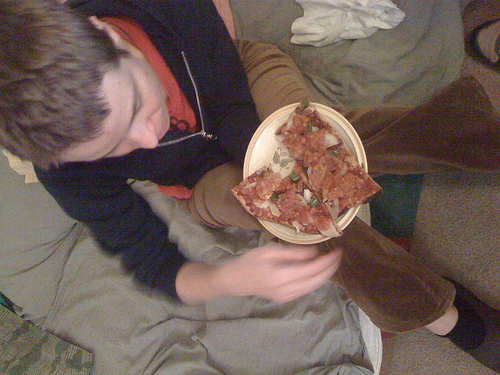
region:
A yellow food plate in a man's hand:
[243, 103, 366, 243]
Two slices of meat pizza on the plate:
[230, 101, 379, 238]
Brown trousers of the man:
[182, 41, 497, 333]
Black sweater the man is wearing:
[34, 0, 260, 299]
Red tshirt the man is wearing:
[98, 15, 195, 198]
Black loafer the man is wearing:
[437, 295, 485, 351]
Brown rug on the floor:
[389, 0, 499, 374]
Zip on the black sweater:
[158, 48, 215, 147]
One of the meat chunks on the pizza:
[276, 188, 303, 217]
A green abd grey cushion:
[0, 305, 92, 374]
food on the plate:
[227, 100, 380, 233]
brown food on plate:
[233, 111, 351, 250]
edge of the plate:
[236, 107, 282, 157]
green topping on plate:
[278, 159, 312, 191]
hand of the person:
[252, 224, 351, 304]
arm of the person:
[95, 154, 222, 326]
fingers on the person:
[286, 235, 360, 303]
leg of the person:
[351, 189, 486, 374]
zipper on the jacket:
[176, 99, 231, 171]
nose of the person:
[123, 99, 173, 172]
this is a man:
[5, 14, 488, 372]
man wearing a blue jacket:
[17, 8, 309, 318]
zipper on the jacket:
[128, 27, 230, 181]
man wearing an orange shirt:
[89, 16, 231, 224]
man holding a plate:
[213, 76, 373, 255]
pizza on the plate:
[227, 87, 377, 252]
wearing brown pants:
[200, 30, 490, 347]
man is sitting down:
[12, 27, 491, 361]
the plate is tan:
[217, 94, 397, 271]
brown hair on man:
[8, 5, 167, 187]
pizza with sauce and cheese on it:
[236, 135, 323, 227]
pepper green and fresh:
[301, 190, 323, 210]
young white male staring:
[40, 20, 230, 199]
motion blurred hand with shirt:
[137, 236, 342, 323]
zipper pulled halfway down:
[180, 84, 220, 161]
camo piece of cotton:
[0, 311, 92, 373]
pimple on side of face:
[133, 60, 152, 83]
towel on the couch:
[280, 0, 428, 58]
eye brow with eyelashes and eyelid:
[122, 80, 148, 130]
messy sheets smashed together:
[147, 300, 352, 373]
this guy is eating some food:
[13, 12, 463, 342]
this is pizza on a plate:
[221, 112, 379, 240]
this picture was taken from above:
[28, 32, 465, 327]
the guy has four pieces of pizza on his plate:
[218, 104, 403, 246]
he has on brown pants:
[206, 65, 479, 328]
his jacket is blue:
[50, 16, 247, 294]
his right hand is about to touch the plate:
[231, 202, 374, 312]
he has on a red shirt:
[99, 14, 213, 156]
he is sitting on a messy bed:
[11, 192, 446, 372]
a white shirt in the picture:
[278, 1, 418, 50]